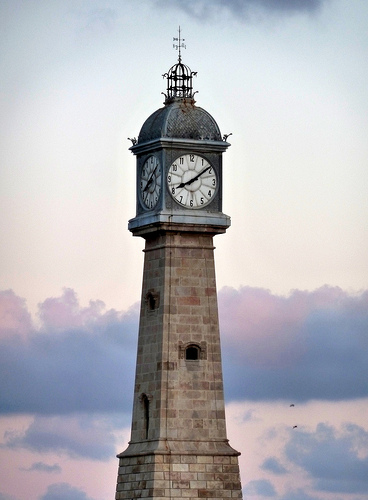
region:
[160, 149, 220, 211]
Clock in tower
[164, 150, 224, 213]
Clock numerals are cardinal numbers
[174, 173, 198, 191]
Hour hand of clock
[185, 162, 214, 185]
Minute hand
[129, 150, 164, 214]
Clock on left side of tower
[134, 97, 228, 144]
Tower roof is black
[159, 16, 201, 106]
Ornament on top of tower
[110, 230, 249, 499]
Tower is made of bricks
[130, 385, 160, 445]
Small window on tower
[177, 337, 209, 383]
Small window under clock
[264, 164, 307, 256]
The color of the sky is a very light pink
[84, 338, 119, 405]
The color of the clouds is a very subtle blue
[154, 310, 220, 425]
The color of the brick is brown as well as white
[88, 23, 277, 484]
This photo was taken in London, England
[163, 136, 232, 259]
The numbers on this clock are gray in color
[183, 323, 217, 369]
There is a window opening on this tower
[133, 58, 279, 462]
This photo was taken in early evening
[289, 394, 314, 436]
The birds that are flying are very dark black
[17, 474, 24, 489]
There is a pink shade that is very visible in the sky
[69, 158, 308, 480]
Jason Zander is the person who took this photo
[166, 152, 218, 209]
a clock on top of the tower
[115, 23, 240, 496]
a tower clocks base is built of bricks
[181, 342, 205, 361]
a window on the clock tower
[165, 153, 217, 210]
the clock face is white with black numbers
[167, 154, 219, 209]
the time displayed on the clock is 8:09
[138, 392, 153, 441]
an archway on the side of the tower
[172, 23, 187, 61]
a weather vane on the top of the clock tower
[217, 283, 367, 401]
grey clouds in the sky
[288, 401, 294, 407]
birds flying in the distance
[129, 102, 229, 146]
the roof of the clock tower is metal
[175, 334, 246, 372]
A small triangle window on side of brick tower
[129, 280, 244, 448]
On this brick tower are many open windows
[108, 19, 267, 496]
A tall brick bell tower lingers behind a cloudy sky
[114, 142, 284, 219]
A numeral clock on top of a bell tower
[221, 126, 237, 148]
A camera hangs from a towering clock - bell tower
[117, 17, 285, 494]
The clock-tower is made out of brick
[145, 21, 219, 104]
At the top of the bell tower is a cross metal figure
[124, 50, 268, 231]
At the top of the tower where the numeral clock hangs is made of granite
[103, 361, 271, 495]
A large window on side of brick bell-tower and a cloudy blue sky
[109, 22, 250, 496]
This brick clock-bell tower has three windows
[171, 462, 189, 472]
a white brick on the tower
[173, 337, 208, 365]
a window on the tower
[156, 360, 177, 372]
a brown brick on the tower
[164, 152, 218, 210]
a white clock face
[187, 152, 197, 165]
a number on the clock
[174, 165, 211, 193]
the hands of the clock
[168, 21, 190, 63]
the tip of the tower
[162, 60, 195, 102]
a cage on the tower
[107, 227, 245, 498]
a tall brick tower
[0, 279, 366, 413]
a cloud in the sky